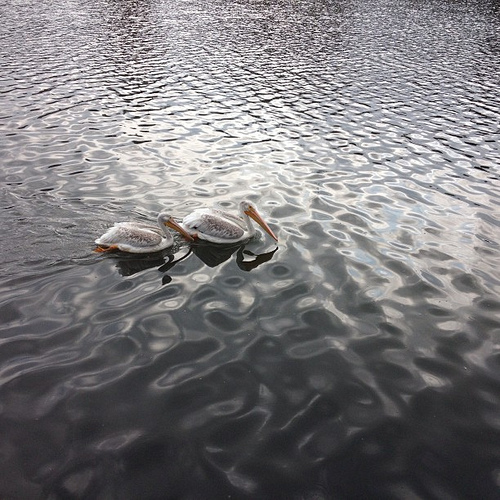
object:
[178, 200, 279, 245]
bird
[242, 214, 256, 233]
neck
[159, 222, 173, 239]
neck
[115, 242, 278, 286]
birds shadow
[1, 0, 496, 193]
water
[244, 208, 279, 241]
beak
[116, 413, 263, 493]
water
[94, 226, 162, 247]
wing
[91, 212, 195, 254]
bird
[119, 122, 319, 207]
glare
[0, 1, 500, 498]
water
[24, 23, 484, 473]
water